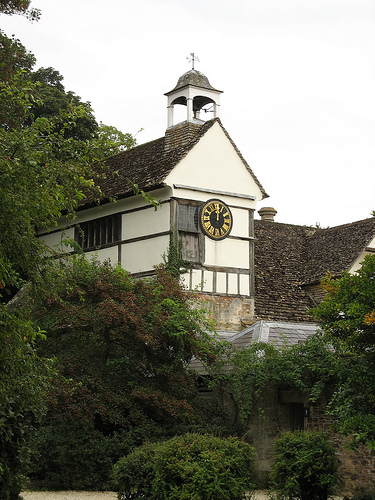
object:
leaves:
[80, 414, 98, 436]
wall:
[32, 189, 171, 285]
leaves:
[182, 445, 199, 463]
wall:
[305, 399, 372, 497]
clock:
[197, 196, 233, 242]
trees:
[0, 0, 374, 489]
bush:
[112, 432, 256, 499]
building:
[0, 51, 370, 491]